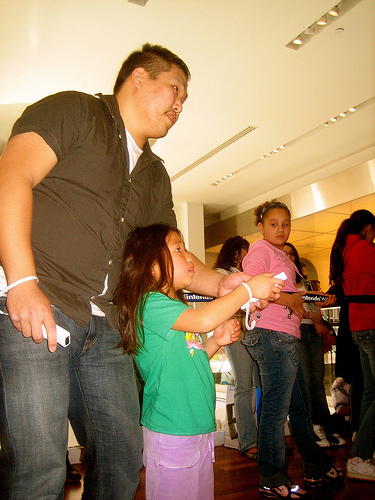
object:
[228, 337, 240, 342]
finger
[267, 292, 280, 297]
finger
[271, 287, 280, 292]
finger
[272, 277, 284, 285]
finger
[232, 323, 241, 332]
finger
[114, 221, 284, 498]
person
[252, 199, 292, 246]
head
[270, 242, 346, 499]
person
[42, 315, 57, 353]
finger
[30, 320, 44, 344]
finger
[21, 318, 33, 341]
finger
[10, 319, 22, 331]
finger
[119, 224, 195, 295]
person head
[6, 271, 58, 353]
hand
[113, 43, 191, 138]
person's head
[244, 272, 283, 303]
hand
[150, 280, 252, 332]
arm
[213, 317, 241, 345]
hand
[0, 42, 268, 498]
man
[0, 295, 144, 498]
pants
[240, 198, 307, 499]
person